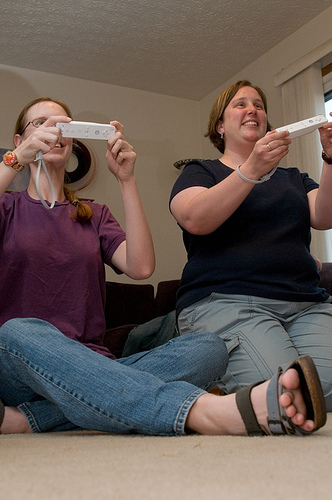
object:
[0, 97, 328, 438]
woman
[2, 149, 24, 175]
watch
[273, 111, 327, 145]
controllers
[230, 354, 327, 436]
sandals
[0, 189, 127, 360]
shirt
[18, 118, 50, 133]
glasses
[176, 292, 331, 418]
pants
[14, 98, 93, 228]
hair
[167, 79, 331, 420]
woman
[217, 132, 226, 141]
earring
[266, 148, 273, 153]
ring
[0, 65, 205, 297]
wall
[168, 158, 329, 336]
shirt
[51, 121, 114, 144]
controller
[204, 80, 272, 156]
hair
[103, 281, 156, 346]
sofa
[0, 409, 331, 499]
floor